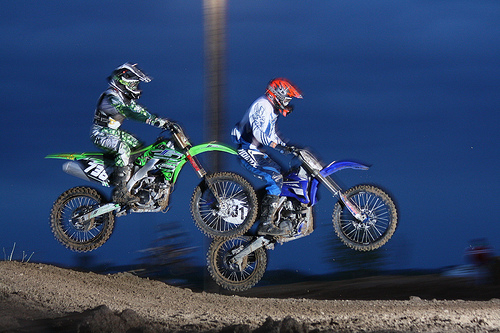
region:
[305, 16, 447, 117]
this is the sky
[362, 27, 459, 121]
the sky is blue in color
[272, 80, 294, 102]
this is a helmet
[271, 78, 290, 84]
the helmet is red in color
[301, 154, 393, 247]
this is a motorbike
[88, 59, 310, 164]
the motorists are two in number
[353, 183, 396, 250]
this is a wheel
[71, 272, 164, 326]
this is the ground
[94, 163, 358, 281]
the motorbikes are two in number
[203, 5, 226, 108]
this is a pole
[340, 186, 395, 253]
wheel of a racing bike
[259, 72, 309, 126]
bike rider helmet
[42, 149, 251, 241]
a racing bike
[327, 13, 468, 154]
blue sky in the background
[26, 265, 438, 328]
a rough road for racking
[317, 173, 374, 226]
motorbike suspension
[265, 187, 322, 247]
racing motor cycle engine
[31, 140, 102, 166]
tail tidies of a motorbike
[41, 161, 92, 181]
motor cycle exhaust pipe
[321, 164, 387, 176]
blue motorbike mud guards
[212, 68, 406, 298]
A man on a motorcycle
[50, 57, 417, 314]
two men on motorcycles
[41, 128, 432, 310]
two motorcycles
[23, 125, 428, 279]
two motorcycles in the air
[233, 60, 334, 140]
a person wearing a red helmet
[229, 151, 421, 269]
A blue motorcycle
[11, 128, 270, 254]
A green motorcycle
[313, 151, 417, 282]
the front wheel of a blue motorcycle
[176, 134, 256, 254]
the front wheel of a green motorcycle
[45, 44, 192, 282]
A person on a green motorcycle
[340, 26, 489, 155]
Sky is blue color.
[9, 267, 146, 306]
Ground is brown color.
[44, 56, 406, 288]
Two bikes are racing.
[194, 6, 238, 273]
Pole is grey color.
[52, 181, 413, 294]
Wheels are black color.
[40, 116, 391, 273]
Bikes are blue and green color.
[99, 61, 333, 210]
People are sitting on the bike.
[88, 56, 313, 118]
People are wearing helmet.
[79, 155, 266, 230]
Numbers on bike.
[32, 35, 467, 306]
Night time picture.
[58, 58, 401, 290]
Two people are racing.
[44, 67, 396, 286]
One bike is green and blue color.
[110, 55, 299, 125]
Two people are wearing helmet.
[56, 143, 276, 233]
Numbers are written on bike.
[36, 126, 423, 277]
Wheels are flying in air.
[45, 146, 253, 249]
Two wheels for bike.